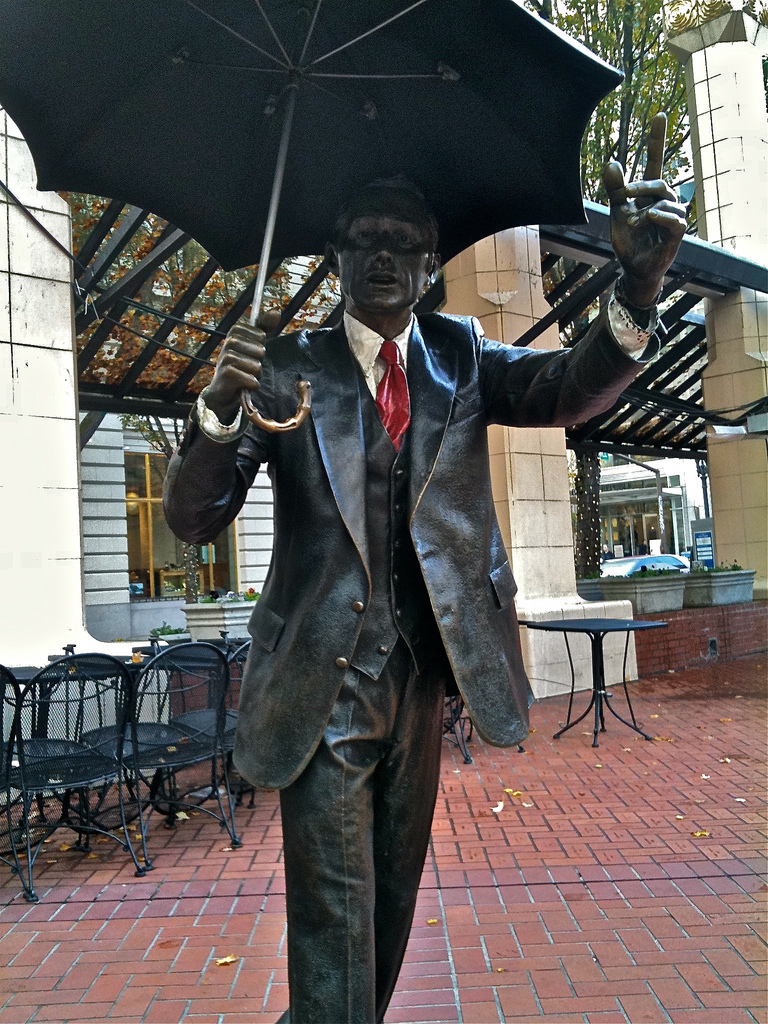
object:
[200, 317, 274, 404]
hand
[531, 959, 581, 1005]
brick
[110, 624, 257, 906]
blackchair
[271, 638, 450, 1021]
leg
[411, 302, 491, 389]
shoulder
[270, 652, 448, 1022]
pants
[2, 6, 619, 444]
umbrella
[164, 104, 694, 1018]
man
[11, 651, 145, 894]
chairs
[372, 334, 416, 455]
tie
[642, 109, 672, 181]
index finger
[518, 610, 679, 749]
table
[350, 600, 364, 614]
button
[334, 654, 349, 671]
button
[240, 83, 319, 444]
handle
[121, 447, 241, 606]
window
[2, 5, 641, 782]
building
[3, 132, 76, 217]
tile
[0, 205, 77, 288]
tile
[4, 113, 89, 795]
wall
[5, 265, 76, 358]
tile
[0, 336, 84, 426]
tile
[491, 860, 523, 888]
brick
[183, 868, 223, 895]
brick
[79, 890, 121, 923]
brick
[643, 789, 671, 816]
brick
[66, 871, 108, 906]
brick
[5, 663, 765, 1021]
sidewalk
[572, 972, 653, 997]
brick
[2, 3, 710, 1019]
statue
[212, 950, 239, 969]
leaf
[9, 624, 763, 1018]
ground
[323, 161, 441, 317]
head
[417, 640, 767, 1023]
ground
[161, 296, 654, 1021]
dress shirt